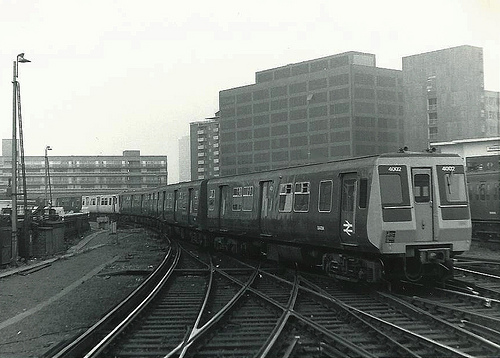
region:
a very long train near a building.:
[50, 141, 483, 284]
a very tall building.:
[217, 50, 402, 185]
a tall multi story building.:
[0, 148, 170, 203]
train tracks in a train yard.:
[48, 220, 498, 356]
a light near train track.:
[6, 41, 34, 268]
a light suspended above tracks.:
[38, 136, 54, 215]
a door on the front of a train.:
[408, 166, 440, 246]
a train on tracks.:
[420, 138, 497, 250]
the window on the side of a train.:
[308, 172, 338, 212]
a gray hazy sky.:
[0, 0, 496, 185]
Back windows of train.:
[370, 153, 477, 224]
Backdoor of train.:
[405, 160, 440, 241]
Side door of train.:
[335, 165, 355, 245]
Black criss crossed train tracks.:
[195, 275, 330, 345]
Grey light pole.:
[10, 45, 30, 195]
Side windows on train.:
[265, 175, 335, 215]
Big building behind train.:
[205, 40, 400, 150]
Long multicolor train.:
[55, 150, 477, 276]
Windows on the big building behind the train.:
[220, 90, 380, 145]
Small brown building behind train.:
[18, 145, 169, 190]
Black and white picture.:
[16, 16, 488, 346]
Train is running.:
[70, 164, 464, 259]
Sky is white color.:
[56, 43, 193, 115]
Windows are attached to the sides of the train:
[94, 193, 341, 220]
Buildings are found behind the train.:
[21, 106, 421, 181]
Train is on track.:
[288, 209, 482, 295]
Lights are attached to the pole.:
[7, 46, 40, 103]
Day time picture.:
[10, 18, 483, 343]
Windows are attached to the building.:
[223, 100, 387, 147]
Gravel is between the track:
[101, 273, 363, 340]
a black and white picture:
[3, 38, 492, 344]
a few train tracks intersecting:
[129, 242, 369, 338]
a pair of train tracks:
[109, 245, 293, 354]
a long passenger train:
[68, 164, 484, 303]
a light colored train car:
[68, 174, 128, 226]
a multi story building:
[9, 134, 179, 229]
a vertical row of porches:
[188, 117, 215, 187]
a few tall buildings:
[145, 42, 499, 187]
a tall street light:
[0, 48, 48, 275]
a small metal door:
[326, 165, 368, 237]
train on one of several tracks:
[30, 5, 480, 337]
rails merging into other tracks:
[110, 250, 431, 340]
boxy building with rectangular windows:
[210, 50, 400, 166]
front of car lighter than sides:
[247, 145, 472, 270]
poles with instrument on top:
[5, 30, 60, 270]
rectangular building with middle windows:
[395, 40, 485, 155]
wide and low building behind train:
[0, 145, 165, 205]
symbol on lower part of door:
[330, 167, 360, 247]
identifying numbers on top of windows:
[370, 160, 466, 215]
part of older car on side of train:
[451, 138, 497, 253]